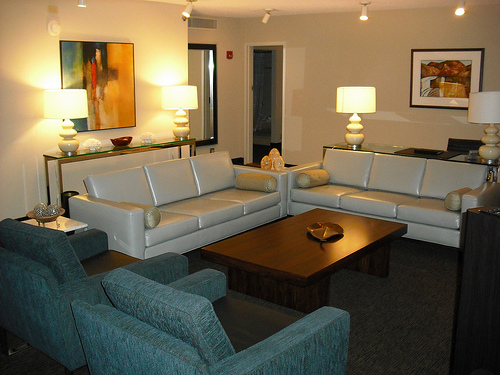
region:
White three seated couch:
[281, 144, 498, 252]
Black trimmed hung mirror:
[186, 39, 221, 149]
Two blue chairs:
[0, 215, 355, 374]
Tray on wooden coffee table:
[195, 204, 412, 307]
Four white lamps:
[40, 84, 499, 169]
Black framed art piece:
[404, 42, 486, 111]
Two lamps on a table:
[40, 82, 200, 215]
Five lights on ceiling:
[72, 0, 499, 26]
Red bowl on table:
[40, 132, 198, 217]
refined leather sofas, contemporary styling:
[62, 130, 499, 272]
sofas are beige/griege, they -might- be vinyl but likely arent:
[58, 138, 499, 266]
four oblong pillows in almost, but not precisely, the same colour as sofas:
[105, 166, 482, 236]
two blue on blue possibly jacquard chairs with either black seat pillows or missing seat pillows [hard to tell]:
[0, 206, 378, 372]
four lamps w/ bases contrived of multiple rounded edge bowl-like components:
[34, 61, 499, 164]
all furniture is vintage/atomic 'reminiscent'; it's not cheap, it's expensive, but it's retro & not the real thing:
[0, 22, 498, 372]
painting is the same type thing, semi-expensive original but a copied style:
[42, 31, 154, 138]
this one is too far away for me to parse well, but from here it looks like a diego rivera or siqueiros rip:
[408, 48, 485, 113]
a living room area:
[15, 31, 497, 334]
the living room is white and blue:
[12, 16, 489, 347]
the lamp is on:
[325, 68, 385, 153]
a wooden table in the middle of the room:
[208, 196, 432, 305]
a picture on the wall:
[37, 27, 156, 169]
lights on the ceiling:
[322, 7, 466, 29]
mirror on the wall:
[179, 39, 233, 150]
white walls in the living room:
[292, 23, 458, 174]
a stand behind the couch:
[38, 126, 212, 170]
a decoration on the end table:
[259, 147, 296, 186]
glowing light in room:
[173, 2, 209, 22]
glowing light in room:
[253, 5, 289, 33]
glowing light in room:
[350, 5, 378, 25]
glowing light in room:
[449, 4, 471, 26]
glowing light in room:
[40, 75, 111, 165]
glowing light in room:
[153, 70, 211, 144]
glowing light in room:
[322, 75, 390, 159]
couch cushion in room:
[116, 191, 206, 253]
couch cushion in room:
[153, 177, 246, 238]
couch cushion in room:
[203, 168, 283, 216]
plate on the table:
[305, 216, 347, 248]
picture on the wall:
[50, 39, 145, 142]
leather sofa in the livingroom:
[56, 150, 299, 256]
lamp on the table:
[157, 77, 201, 141]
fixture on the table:
[25, 197, 67, 231]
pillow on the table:
[296, 162, 329, 187]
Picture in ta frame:
[408, 46, 484, 111]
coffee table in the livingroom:
[194, 203, 409, 285]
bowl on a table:
[107, 126, 141, 155]